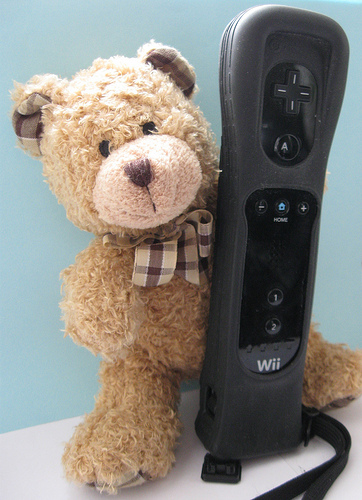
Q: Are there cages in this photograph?
A: No, there are no cages.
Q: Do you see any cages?
A: No, there are no cages.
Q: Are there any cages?
A: No, there are no cages.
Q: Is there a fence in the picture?
A: No, there are no fences.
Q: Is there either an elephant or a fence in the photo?
A: No, there are no fences or elephants.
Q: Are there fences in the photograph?
A: No, there are no fences.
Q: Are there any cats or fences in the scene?
A: No, there are no fences or cats.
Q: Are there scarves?
A: Yes, there is a scarf.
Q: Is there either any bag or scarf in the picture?
A: Yes, there is a scarf.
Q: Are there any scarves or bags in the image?
A: Yes, there is a scarf.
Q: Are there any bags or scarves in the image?
A: Yes, there is a scarf.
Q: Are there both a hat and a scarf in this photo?
A: No, there is a scarf but no hats.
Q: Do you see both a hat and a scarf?
A: No, there is a scarf but no hats.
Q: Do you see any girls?
A: No, there are no girls.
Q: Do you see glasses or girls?
A: No, there are no girls or glasses.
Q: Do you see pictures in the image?
A: No, there are no pictures.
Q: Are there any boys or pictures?
A: No, there are no pictures or boys.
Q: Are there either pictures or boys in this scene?
A: No, there are no pictures or boys.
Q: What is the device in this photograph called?
A: The device is a Wii.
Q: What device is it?
A: The device is a Wii.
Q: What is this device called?
A: This is a Wii.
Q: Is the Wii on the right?
A: Yes, the Wii is on the right of the image.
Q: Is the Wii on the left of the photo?
A: No, the Wii is on the right of the image.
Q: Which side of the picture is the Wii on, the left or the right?
A: The Wii is on the right of the image.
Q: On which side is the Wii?
A: The Wii is on the right of the image.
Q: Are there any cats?
A: No, there are no cats.